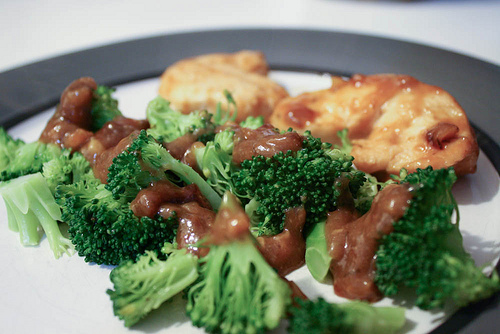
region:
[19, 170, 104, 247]
pieces of raw broccoli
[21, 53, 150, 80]
grey edge of the plate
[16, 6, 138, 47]
white counter top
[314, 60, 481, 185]
piece of cooked potato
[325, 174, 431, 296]
brown sauce on the raw broccoli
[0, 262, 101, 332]
white center part of the plate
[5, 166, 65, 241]
piece of broccoli stem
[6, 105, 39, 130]
black ring around the inner plate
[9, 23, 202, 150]
plate on the counter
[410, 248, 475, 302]
raw broccoli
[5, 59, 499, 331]
food on a white plate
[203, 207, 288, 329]
broccoli on the plate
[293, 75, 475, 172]
meat on the plate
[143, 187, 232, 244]
brown sauce on the food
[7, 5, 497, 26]
the white table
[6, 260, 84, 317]
part of the white plate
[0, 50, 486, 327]
a plate full of food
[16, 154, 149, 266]
green brocolli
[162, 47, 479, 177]
two pieces of meat on the plate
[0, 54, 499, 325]
food stacked on a plate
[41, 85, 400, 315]
the sauce is brown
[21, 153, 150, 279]
the broccoli is green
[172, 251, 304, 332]
the broccoli is green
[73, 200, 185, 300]
the broccoli is green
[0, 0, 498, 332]
Culinary display of food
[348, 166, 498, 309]
Green broccoli on the plate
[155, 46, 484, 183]
Meat next to the broccoli on the plate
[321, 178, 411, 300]
Brown sauce on the broccoli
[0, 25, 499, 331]
Plate with food on the table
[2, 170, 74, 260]
Green broccoli stem on the edge of the plate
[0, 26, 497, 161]
Grey edge lining on the plate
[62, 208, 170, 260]
Green leaf part of the broccoli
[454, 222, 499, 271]
Shadow of the broccoli on the plate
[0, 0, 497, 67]
White table on the back ground